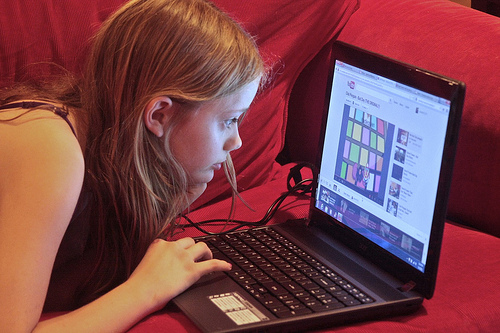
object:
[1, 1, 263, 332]
girl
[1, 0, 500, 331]
couch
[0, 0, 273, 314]
hair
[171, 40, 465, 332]
laptop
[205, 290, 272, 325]
label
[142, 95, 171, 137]
right ear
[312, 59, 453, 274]
screen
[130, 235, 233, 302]
hand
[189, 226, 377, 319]
keyboard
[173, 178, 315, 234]
wires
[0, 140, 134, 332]
arms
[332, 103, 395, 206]
image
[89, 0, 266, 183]
head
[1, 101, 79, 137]
strap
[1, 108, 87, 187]
shoulder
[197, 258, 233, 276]
finger